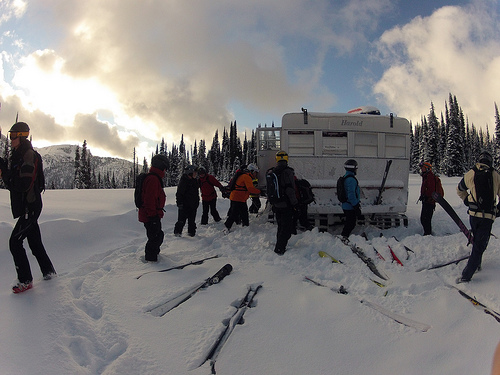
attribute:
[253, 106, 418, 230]
camper — white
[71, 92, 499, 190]
trees — pine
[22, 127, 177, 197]
mountain — snowy, in the distance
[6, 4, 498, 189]
sky — cloudy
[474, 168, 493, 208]
black backpack — large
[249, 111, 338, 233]
camper door — open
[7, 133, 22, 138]
goggles — yellow